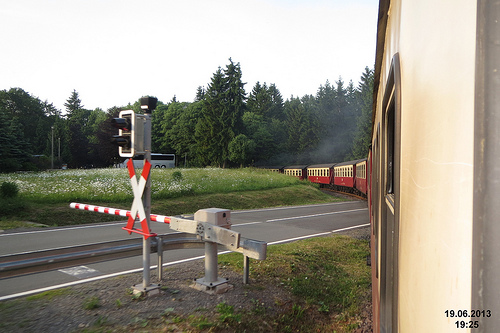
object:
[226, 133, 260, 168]
green trees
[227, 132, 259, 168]
trees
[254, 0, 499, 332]
train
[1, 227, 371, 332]
dirt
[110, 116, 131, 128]
light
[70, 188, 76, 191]
white flowers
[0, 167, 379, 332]
ground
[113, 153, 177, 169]
bus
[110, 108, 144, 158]
signal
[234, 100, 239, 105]
leaves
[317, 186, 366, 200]
tracks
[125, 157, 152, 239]
x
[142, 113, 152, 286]
post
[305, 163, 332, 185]
car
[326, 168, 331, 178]
window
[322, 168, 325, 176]
window